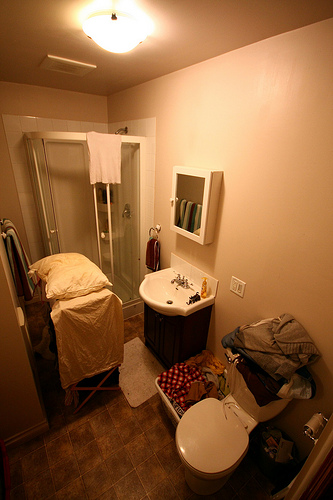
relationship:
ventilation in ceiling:
[43, 55, 96, 78] [1, 1, 331, 94]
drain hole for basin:
[166, 299, 174, 304] [139, 267, 210, 316]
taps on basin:
[172, 273, 186, 288] [139, 267, 210, 316]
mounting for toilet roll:
[303, 410, 331, 444] [304, 413, 325, 432]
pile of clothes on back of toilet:
[221, 314, 316, 407] [175, 347, 310, 495]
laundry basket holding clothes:
[153, 348, 229, 424] [161, 351, 224, 414]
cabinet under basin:
[144, 306, 211, 366] [139, 267, 210, 316]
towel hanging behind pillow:
[4, 222, 34, 300] [32, 253, 112, 300]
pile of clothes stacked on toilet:
[221, 314, 316, 407] [175, 347, 310, 495]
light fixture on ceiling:
[72, 6, 158, 53] [1, 1, 331, 94]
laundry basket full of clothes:
[153, 348, 229, 424] [161, 351, 224, 414]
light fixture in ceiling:
[72, 6, 158, 53] [1, 1, 331, 94]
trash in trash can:
[264, 431, 294, 460] [259, 430, 298, 482]